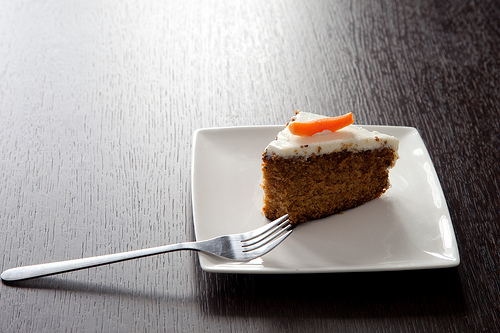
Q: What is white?
A: Frosting on cake.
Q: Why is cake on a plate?
A: To be eaten.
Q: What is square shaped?
A: Plate.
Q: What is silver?
A: Fork.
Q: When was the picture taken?
A: Daytime.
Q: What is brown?
A: Table.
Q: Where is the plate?
A: On a table.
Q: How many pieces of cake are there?
A: One.